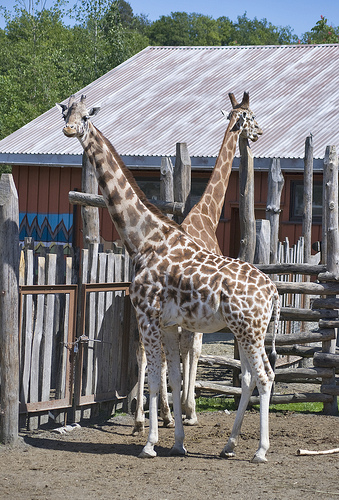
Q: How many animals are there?
A: 2.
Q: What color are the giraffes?
A: White and brown.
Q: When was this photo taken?
A: During the day.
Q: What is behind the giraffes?
A: A building.